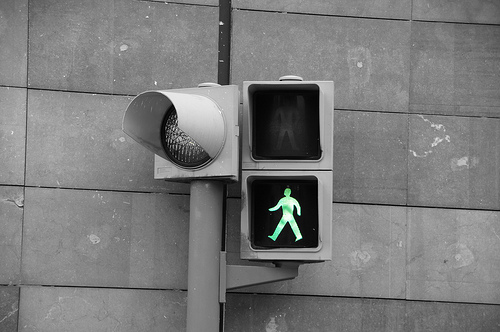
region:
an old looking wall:
[1, 0, 491, 316]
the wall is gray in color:
[6, 9, 492, 317]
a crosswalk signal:
[242, 170, 327, 258]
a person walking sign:
[241, 171, 323, 257]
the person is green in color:
[248, 169, 322, 249]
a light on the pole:
[119, 85, 234, 172]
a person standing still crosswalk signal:
[242, 84, 324, 159]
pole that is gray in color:
[182, 181, 224, 330]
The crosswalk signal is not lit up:
[247, 89, 319, 163]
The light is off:
[126, 89, 227, 173]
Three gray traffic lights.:
[121, 75, 336, 262]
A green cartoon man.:
[266, 184, 303, 242]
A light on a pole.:
[121, 81, 239, 330]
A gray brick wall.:
[1, 0, 497, 329]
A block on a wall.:
[228, 8, 413, 115]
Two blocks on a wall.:
[22, 1, 221, 196]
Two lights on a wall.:
[238, 73, 330, 263]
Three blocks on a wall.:
[18, 1, 220, 290]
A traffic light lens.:
[159, 104, 212, 169]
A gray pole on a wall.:
[183, 178, 225, 325]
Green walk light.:
[251, 176, 310, 247]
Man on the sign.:
[256, 177, 311, 246]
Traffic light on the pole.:
[126, 75, 336, 281]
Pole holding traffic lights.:
[176, 190, 248, 327]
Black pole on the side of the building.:
[212, 0, 234, 82]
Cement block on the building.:
[15, 179, 188, 296]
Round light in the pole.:
[155, 100, 215, 167]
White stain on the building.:
[410, 108, 455, 170]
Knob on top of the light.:
[277, 72, 305, 81]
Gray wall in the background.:
[1, 1, 495, 330]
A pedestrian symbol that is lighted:
[268, 185, 306, 245]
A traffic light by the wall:
[123, 58, 333, 259]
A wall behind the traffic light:
[0, 1, 497, 330]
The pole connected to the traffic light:
[188, 180, 231, 330]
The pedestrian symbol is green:
[266, 183, 303, 240]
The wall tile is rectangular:
[24, 85, 199, 195]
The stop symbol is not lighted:
[247, 85, 322, 160]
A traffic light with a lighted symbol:
[130, 85, 327, 267]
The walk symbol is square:
[242, 175, 319, 246]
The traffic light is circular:
[151, 91, 216, 163]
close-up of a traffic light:
[31, 10, 456, 310]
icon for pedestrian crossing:
[245, 175, 315, 250]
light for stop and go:
[120, 80, 235, 180]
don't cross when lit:
[245, 85, 315, 155]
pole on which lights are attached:
[180, 180, 225, 325]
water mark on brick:
[410, 115, 450, 155]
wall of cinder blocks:
[5, 5, 120, 325]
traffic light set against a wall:
[60, 10, 400, 285]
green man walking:
[255, 180, 312, 242]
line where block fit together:
[12, 10, 37, 176]